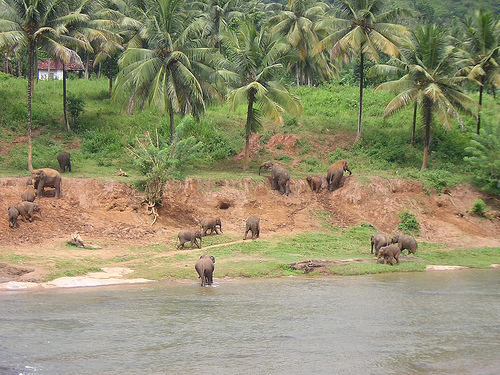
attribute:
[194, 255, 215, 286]
elephant — brown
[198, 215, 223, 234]
elephant — walking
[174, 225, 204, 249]
elephant — walking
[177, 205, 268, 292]
elephants — herd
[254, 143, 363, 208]
elephants — herd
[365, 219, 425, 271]
elephants — herd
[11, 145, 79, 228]
elephants — herd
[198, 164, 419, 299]
elephants — walking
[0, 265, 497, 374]
lake — flowing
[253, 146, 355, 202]
elephants — climbing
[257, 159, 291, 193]
elephant — walking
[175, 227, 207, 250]
elephant — dark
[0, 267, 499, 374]
water — brown, murky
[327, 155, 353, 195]
elephants — enjoying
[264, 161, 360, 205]
elephants — enjoying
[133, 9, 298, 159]
trees — tropical, palm